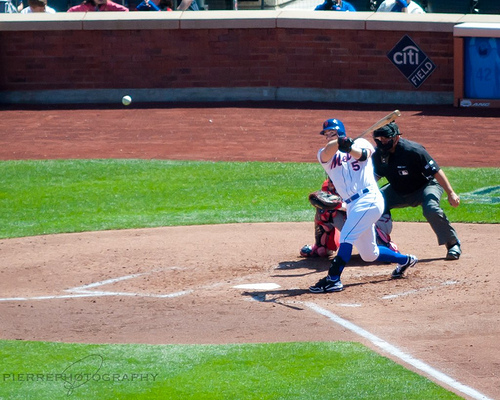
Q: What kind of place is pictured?
A: It is a field.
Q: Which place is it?
A: It is a field.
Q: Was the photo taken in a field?
A: Yes, it was taken in a field.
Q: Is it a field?
A: Yes, it is a field.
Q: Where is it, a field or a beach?
A: It is a field.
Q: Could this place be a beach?
A: No, it is a field.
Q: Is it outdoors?
A: Yes, it is outdoors.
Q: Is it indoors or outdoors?
A: It is outdoors.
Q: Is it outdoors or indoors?
A: It is outdoors.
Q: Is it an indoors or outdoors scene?
A: It is outdoors.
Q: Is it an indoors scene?
A: No, it is outdoors.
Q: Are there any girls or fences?
A: No, there are no fences or girls.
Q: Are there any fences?
A: No, there are no fences.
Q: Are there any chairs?
A: No, there are no chairs.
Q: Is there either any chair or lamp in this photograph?
A: No, there are no chairs or lamps.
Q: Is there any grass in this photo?
A: Yes, there is grass.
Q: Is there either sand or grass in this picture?
A: Yes, there is grass.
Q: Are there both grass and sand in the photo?
A: No, there is grass but no sand.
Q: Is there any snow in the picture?
A: No, there is no snow.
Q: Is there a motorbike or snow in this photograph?
A: No, there are no snow or motorcycles.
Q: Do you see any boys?
A: No, there are no boys.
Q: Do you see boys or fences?
A: No, there are no boys or fences.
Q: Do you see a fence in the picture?
A: No, there are no fences.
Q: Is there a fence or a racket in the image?
A: No, there are no fences or rackets.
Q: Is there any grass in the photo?
A: Yes, there is grass.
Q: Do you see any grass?
A: Yes, there is grass.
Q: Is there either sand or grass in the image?
A: Yes, there is grass.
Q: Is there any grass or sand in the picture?
A: Yes, there is grass.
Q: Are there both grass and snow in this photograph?
A: No, there is grass but no snow.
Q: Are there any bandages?
A: No, there are no bandages.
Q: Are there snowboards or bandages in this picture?
A: No, there are no bandages or snowboards.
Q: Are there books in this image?
A: No, there are no books.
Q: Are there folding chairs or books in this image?
A: No, there are no books or folding chairs.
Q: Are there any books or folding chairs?
A: No, there are no books or folding chairs.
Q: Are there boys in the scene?
A: No, there are no boys.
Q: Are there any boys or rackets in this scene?
A: No, there are no boys or rackets.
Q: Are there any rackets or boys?
A: No, there are no boys or rackets.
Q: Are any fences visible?
A: No, there are no fences.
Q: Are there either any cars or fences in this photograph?
A: No, there are no fences or cars.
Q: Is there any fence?
A: No, there are no fences.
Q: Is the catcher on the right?
A: Yes, the catcher is on the right of the image.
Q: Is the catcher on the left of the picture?
A: No, the catcher is on the right of the image.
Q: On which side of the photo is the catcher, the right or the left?
A: The catcher is on the right of the image.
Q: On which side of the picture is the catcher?
A: The catcher is on the right of the image.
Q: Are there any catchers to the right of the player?
A: Yes, there is a catcher to the right of the player.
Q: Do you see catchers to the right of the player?
A: Yes, there is a catcher to the right of the player.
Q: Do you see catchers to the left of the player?
A: No, the catcher is to the right of the player.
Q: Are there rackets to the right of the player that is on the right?
A: No, there is a catcher to the right of the player.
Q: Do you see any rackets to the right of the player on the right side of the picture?
A: No, there is a catcher to the right of the player.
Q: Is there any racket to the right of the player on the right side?
A: No, there is a catcher to the right of the player.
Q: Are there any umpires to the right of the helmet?
A: No, there is a catcher to the right of the helmet.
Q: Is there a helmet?
A: Yes, there is a helmet.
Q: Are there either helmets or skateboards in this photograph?
A: Yes, there is a helmet.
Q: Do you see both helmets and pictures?
A: No, there is a helmet but no pictures.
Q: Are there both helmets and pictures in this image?
A: No, there is a helmet but no pictures.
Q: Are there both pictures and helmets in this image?
A: No, there is a helmet but no pictures.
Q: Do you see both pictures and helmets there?
A: No, there is a helmet but no pictures.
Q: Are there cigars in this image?
A: No, there are no cigars.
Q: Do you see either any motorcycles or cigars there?
A: No, there are no cigars or motorcycles.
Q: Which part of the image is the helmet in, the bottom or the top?
A: The helmet is in the top of the image.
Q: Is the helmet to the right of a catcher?
A: No, the helmet is to the left of a catcher.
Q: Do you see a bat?
A: Yes, there is a bat.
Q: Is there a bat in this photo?
A: Yes, there is a bat.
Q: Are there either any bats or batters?
A: Yes, there is a bat.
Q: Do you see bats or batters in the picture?
A: Yes, there is a bat.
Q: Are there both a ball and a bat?
A: Yes, there are both a bat and a ball.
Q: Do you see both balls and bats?
A: Yes, there are both a bat and a ball.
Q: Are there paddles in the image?
A: No, there are no paddles.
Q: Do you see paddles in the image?
A: No, there are no paddles.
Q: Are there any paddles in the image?
A: No, there are no paddles.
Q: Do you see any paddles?
A: No, there are no paddles.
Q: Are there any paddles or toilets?
A: No, there are no paddles or toilets.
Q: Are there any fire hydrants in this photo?
A: No, there are no fire hydrants.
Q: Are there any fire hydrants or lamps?
A: No, there are no fire hydrants or lamps.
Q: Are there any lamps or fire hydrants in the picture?
A: No, there are no fire hydrants or lamps.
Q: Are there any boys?
A: No, there are no boys.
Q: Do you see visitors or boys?
A: No, there are no boys or visitors.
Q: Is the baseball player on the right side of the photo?
A: Yes, the player is on the right of the image.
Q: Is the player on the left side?
A: No, the player is on the right of the image.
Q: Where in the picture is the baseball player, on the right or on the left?
A: The player is on the right of the image.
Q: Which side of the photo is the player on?
A: The player is on the right of the image.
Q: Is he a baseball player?
A: Yes, this is a baseball player.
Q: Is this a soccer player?
A: No, this is a baseball player.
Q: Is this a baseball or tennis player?
A: This is a baseball player.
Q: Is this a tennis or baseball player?
A: This is a baseball player.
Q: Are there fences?
A: No, there are no fences.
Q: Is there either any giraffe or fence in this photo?
A: No, there are no fences or giraffes.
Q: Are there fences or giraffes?
A: No, there are no fences or giraffes.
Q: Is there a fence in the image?
A: No, there are no fences.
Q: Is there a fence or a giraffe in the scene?
A: No, there are no fences or giraffes.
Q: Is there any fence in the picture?
A: No, there are no fences.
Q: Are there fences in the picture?
A: No, there are no fences.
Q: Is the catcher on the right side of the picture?
A: Yes, the catcher is on the right of the image.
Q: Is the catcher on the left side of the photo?
A: No, the catcher is on the right of the image.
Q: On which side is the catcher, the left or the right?
A: The catcher is on the right of the image.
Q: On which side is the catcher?
A: The catcher is on the right of the image.